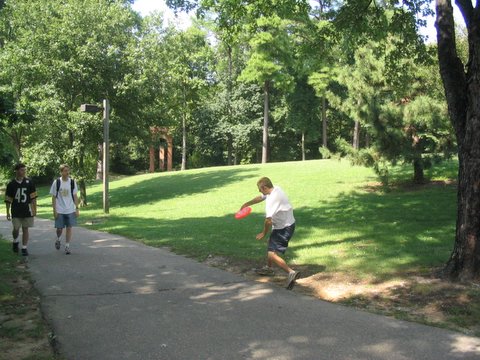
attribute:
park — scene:
[14, 20, 474, 356]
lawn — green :
[146, 160, 425, 259]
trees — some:
[51, 35, 421, 166]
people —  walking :
[23, 164, 91, 225]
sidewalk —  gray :
[79, 245, 229, 352]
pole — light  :
[81, 96, 138, 193]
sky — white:
[141, 4, 231, 40]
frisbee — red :
[218, 194, 266, 228]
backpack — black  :
[44, 171, 77, 219]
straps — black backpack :
[44, 171, 77, 219]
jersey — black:
[7, 182, 46, 220]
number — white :
[7, 182, 46, 220]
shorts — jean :
[53, 205, 90, 229]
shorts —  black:
[236, 238, 307, 270]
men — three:
[9, 162, 356, 297]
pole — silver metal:
[83, 98, 137, 204]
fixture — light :
[69, 104, 126, 227]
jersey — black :
[3, 162, 42, 287]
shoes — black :
[3, 237, 42, 259]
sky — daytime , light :
[137, 7, 478, 55]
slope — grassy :
[37, 144, 445, 259]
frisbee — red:
[214, 166, 293, 268]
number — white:
[8, 181, 42, 215]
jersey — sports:
[8, 181, 42, 215]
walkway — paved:
[15, 191, 441, 322]